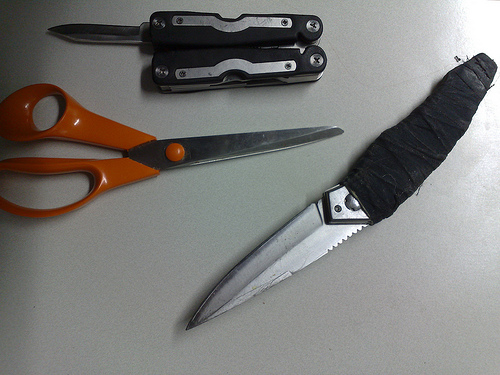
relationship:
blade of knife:
[179, 198, 326, 346] [189, 46, 480, 346]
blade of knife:
[48, 17, 154, 55] [38, 12, 321, 40]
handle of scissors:
[4, 83, 157, 225] [4, 83, 348, 219]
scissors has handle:
[4, 83, 348, 219] [4, 83, 157, 225]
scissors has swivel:
[4, 83, 348, 219] [160, 142, 186, 171]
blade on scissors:
[161, 115, 345, 171] [4, 83, 348, 219]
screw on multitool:
[309, 47, 328, 77] [144, 7, 328, 101]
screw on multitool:
[304, 10, 324, 39] [144, 7, 328, 101]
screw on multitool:
[147, 7, 174, 34] [144, 7, 328, 101]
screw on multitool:
[150, 60, 171, 85] [144, 7, 328, 101]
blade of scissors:
[161, 115, 345, 171] [4, 83, 348, 219]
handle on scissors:
[4, 83, 157, 225] [4, 83, 348, 219]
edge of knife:
[261, 235, 350, 303] [189, 46, 480, 346]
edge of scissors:
[257, 140, 333, 159] [4, 83, 348, 219]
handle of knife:
[372, 51, 479, 217] [189, 46, 480, 346]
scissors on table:
[4, 83, 348, 219] [337, 15, 384, 95]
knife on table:
[189, 46, 480, 346] [337, 15, 384, 95]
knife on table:
[38, 12, 321, 40] [337, 15, 384, 95]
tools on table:
[114, 8, 380, 298] [337, 15, 384, 95]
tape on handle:
[432, 55, 469, 163] [372, 51, 479, 217]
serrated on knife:
[323, 206, 379, 257] [189, 46, 480, 346]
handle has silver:
[167, 8, 257, 97] [208, 12, 250, 39]